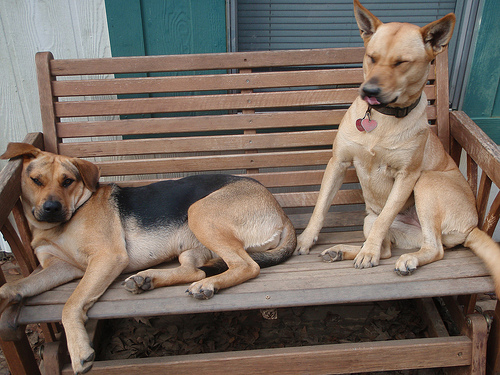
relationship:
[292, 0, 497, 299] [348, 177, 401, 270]
dog sitting leg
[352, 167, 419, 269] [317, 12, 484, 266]
leg sitting dog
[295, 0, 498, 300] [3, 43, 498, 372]
dog on bench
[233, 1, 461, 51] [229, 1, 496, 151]
gray blinds on window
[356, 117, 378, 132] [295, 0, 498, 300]
tag on dog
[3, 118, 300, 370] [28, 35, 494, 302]
dog lying on bench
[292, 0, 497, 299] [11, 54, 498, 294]
dog sitting on bench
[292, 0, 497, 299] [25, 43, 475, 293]
dog behind becnh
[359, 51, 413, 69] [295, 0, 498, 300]
eyes on dog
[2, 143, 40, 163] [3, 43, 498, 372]
ear on bench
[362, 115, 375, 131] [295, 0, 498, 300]
tag on dog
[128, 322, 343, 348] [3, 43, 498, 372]
leaves under bench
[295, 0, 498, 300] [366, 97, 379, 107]
dog with tongue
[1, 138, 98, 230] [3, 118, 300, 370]
head of a dog